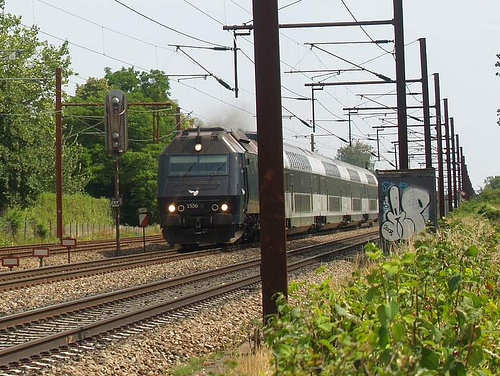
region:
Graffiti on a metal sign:
[377, 172, 429, 247]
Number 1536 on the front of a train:
[183, 200, 199, 210]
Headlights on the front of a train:
[158, 197, 233, 212]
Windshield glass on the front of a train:
[163, 154, 226, 176]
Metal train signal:
[101, 85, 124, 251]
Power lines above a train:
[3, 2, 480, 171]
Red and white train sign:
[136, 205, 149, 247]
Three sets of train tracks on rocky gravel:
[3, 227, 174, 354]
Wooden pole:
[253, 89, 294, 316]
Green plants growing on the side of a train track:
[346, 275, 486, 374]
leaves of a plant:
[370, 282, 419, 345]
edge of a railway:
[142, 327, 177, 360]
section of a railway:
[108, 286, 135, 319]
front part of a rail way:
[189, 149, 216, 197]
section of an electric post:
[260, 142, 270, 188]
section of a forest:
[18, 152, 30, 191]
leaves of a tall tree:
[31, 147, 40, 170]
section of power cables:
[331, 95, 341, 116]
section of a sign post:
[381, 191, 415, 254]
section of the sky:
[467, 98, 476, 126]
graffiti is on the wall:
[378, 170, 439, 251]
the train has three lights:
[167, 142, 231, 212]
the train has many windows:
[158, 127, 378, 241]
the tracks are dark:
[2, 231, 378, 369]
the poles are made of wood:
[55, 0, 475, 329]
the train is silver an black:
[160, 130, 376, 248]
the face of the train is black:
[157, 129, 247, 244]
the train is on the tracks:
[155, 136, 379, 248]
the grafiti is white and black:
[384, 185, 429, 243]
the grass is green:
[266, 174, 496, 372]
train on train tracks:
[30, 74, 462, 321]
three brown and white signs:
[2, 194, 97, 301]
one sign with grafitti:
[364, 156, 448, 273]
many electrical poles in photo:
[156, 0, 493, 213]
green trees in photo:
[2, 13, 208, 244]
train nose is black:
[149, 140, 247, 265]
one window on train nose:
[142, 126, 239, 202]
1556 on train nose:
[154, 166, 250, 256]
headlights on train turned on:
[151, 171, 261, 266]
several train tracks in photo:
[30, 204, 261, 374]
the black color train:
[152, 103, 383, 248]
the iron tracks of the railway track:
[77, 274, 230, 339]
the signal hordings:
[365, 164, 443, 255]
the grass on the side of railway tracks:
[329, 258, 466, 360]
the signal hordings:
[91, 81, 134, 259]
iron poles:
[241, 8, 298, 367]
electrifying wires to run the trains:
[284, 22, 376, 147]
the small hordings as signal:
[30, 225, 83, 271]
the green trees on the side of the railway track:
[55, 56, 162, 233]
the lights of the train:
[165, 196, 182, 223]